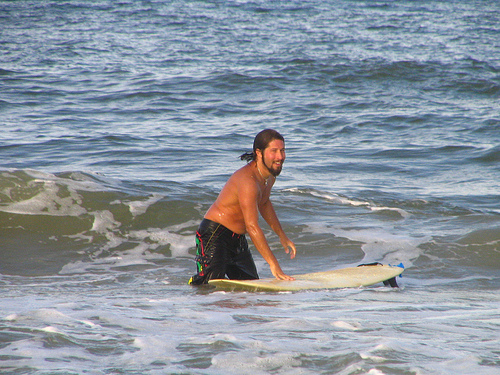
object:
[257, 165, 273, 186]
necklace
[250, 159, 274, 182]
neck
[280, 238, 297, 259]
hand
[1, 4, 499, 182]
ripples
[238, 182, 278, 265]
arms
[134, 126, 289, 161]
floor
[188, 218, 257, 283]
man wearing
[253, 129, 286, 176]
head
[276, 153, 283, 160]
nose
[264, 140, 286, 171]
face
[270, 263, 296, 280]
hand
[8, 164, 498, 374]
sea foam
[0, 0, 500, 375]
water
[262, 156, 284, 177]
beard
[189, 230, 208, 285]
stripe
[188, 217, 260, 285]
shorts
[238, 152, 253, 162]
ponytail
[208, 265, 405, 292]
board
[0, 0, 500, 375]
ocean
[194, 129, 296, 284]
man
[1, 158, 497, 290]
wave